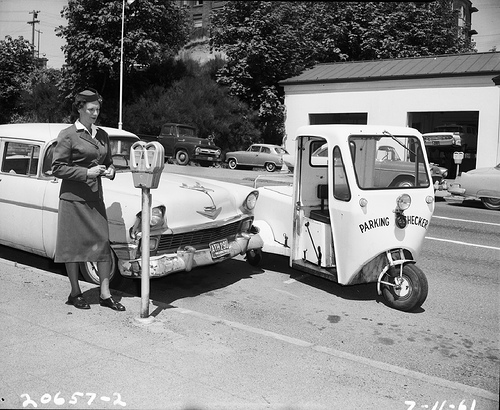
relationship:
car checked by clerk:
[3, 122, 263, 288] [48, 89, 126, 312]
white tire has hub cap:
[176, 149, 188, 164] [180, 152, 185, 162]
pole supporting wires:
[20, 8, 48, 59] [0, 6, 64, 44]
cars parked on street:
[144, 122, 289, 171] [107, 156, 499, 395]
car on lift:
[422, 131, 469, 146] [418, 145, 459, 175]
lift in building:
[418, 145, 459, 175] [277, 50, 500, 180]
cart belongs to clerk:
[257, 122, 430, 310] [48, 87, 124, 308]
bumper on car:
[124, 230, 257, 278] [3, 122, 263, 288]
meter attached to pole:
[129, 140, 164, 189] [137, 186, 155, 318]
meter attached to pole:
[127, 135, 146, 187] [137, 186, 155, 318]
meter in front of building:
[426, 144, 475, 204] [277, 50, 500, 180]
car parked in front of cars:
[225, 143, 288, 171] [137, 122, 221, 168]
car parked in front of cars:
[3, 122, 263, 288] [137, 122, 221, 168]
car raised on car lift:
[415, 124, 470, 153] [426, 148, 474, 163]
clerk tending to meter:
[48, 89, 126, 312] [125, 138, 162, 318]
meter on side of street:
[453, 151, 466, 176] [0, 151, 494, 409]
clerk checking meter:
[48, 89, 126, 312] [126, 136, 161, 190]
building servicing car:
[277, 50, 500, 180] [423, 114, 482, 164]